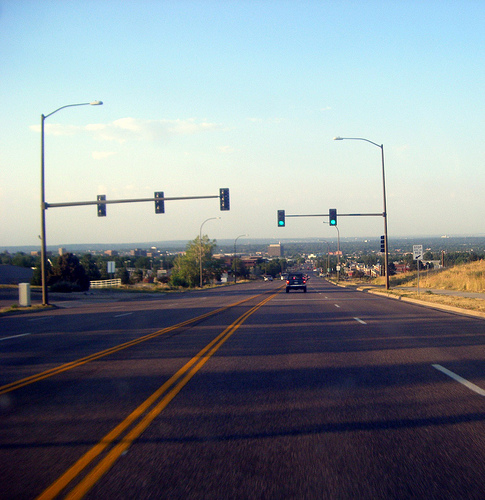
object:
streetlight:
[277, 209, 285, 227]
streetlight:
[329, 208, 338, 226]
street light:
[329, 208, 338, 226]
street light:
[277, 209, 286, 227]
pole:
[381, 143, 390, 289]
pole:
[46, 195, 220, 208]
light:
[219, 188, 230, 211]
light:
[154, 191, 165, 214]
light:
[97, 194, 107, 217]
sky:
[0, 0, 485, 243]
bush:
[49, 252, 91, 292]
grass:
[371, 260, 485, 311]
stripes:
[431, 362, 485, 398]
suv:
[285, 272, 307, 293]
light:
[277, 209, 286, 227]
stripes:
[335, 303, 340, 308]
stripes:
[114, 312, 132, 317]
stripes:
[169, 303, 178, 306]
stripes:
[0, 332, 31, 342]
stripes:
[324, 296, 327, 298]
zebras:
[353, 316, 367, 325]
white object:
[19, 282, 31, 306]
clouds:
[274, 114, 485, 225]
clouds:
[106, 115, 221, 144]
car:
[285, 271, 307, 292]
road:
[0, 270, 485, 500]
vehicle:
[285, 272, 307, 293]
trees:
[388, 261, 397, 281]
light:
[303, 281, 306, 284]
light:
[286, 280, 290, 284]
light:
[329, 208, 337, 226]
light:
[277, 209, 285, 227]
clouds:
[50, 122, 104, 167]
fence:
[90, 278, 122, 288]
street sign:
[412, 244, 423, 260]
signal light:
[330, 219, 336, 224]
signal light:
[279, 220, 284, 225]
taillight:
[286, 280, 289, 284]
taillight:
[303, 280, 306, 283]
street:
[1, 272, 485, 500]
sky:
[0, 0, 485, 247]